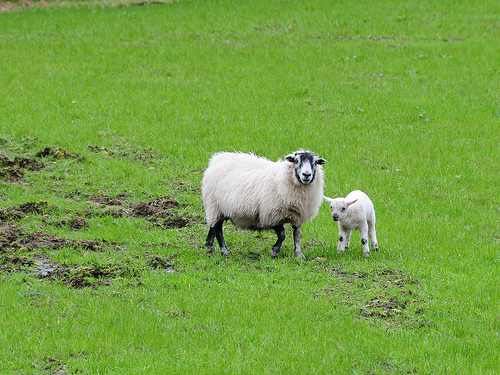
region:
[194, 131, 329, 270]
This is a sheep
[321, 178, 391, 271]
This is a sheep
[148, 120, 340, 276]
this is a sheep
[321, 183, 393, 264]
this is a sheep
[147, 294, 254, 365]
this is a patch of grass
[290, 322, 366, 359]
this is a patch of grass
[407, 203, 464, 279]
this is a patch of grass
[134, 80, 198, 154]
this is a patch of grass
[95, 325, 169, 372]
this is a patch of grass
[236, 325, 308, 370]
this is a patch of grass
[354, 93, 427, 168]
this is a patch of grass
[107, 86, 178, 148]
this is a patch of grass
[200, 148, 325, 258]
a mother sheep in the field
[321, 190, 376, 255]
a baby lamb with the mother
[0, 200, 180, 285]
a muddy area in the field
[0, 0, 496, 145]
green grass for grazing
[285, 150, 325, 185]
the sheep's black and white face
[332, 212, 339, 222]
the baby lambs black nose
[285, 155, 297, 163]
the mother sheep has black ears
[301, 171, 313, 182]
the mother sheep's black nose and mouth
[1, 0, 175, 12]
a brown area in the grass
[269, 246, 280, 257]
the sheep's grey hooves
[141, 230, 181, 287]
a hole in the ground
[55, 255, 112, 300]
a hole in the ground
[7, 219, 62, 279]
a hole in the ground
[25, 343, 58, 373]
a hole in the ground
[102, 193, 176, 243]
a hole in the ground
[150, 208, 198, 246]
a hole in the ground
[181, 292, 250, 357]
a patch of green grass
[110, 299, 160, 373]
a patch of green grass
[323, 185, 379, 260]
a white lamb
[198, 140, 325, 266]
a black and white sheep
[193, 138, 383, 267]
a sheep with it's baby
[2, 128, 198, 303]
patches of dirt is the grass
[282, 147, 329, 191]
the sheep's face is black and white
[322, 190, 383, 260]
the lamb has black patches on it's legs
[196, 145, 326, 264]
the sheep has black legs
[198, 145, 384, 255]
a lamb and a sheep standing together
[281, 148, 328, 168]
the sheep has ears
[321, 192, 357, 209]
the lamb has white ears